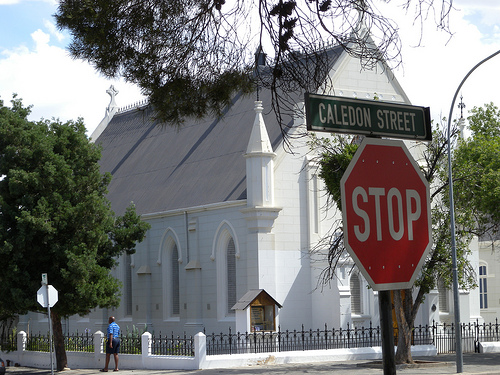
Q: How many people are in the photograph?
A: One.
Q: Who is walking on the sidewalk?
A: The man.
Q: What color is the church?
A: White.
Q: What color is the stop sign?
A: Red.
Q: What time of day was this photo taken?
A: Day time.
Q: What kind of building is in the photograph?
A: A church.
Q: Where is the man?
A: On the sidewalk.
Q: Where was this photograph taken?
A: Caledon Street.